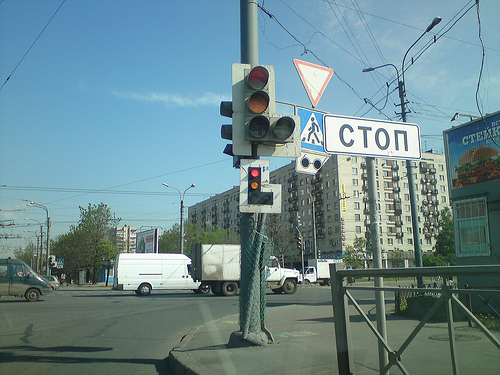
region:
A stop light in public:
[231, 63, 302, 158]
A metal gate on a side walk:
[327, 260, 498, 373]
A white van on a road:
[113, 250, 213, 292]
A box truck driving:
[193, 243, 300, 292]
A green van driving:
[0, 258, 50, 300]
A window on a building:
[350, 164, 358, 175]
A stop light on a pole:
[238, 157, 281, 214]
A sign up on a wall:
[452, 198, 492, 256]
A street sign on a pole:
[321, 112, 421, 374]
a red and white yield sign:
[291, 58, 333, 106]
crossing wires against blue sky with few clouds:
[5, 1, 495, 231]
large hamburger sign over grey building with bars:
[440, 106, 495, 303]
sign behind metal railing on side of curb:
[320, 265, 490, 370]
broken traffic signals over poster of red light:
[225, 10, 295, 340]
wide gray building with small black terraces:
[190, 156, 445, 251]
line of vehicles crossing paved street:
[2, 247, 349, 294]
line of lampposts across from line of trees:
[15, 191, 110, 281]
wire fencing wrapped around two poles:
[231, 215, 271, 340]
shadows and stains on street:
[0, 306, 160, 366]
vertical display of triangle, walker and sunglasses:
[292, 55, 327, 186]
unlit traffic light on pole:
[231, 61, 298, 153]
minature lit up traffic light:
[238, 153, 287, 220]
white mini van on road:
[111, 247, 203, 298]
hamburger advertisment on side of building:
[448, 133, 496, 189]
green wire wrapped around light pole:
[233, 215, 270, 332]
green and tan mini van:
[1, 255, 48, 304]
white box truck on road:
[198, 244, 300, 296]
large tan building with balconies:
[190, 135, 446, 267]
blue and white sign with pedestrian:
[300, 108, 333, 148]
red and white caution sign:
[293, 57, 338, 107]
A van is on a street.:
[109, 246, 206, 302]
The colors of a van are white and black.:
[110, 250, 205, 293]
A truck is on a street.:
[191, 238, 302, 299]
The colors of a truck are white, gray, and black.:
[191, 241, 304, 298]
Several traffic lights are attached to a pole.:
[215, 58, 300, 217]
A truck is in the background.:
[297, 250, 347, 288]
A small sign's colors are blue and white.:
[292, 99, 330, 156]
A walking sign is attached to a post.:
[290, 100, 328, 155]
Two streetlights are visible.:
[355, 11, 445, 121]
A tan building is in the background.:
[161, 137, 458, 289]